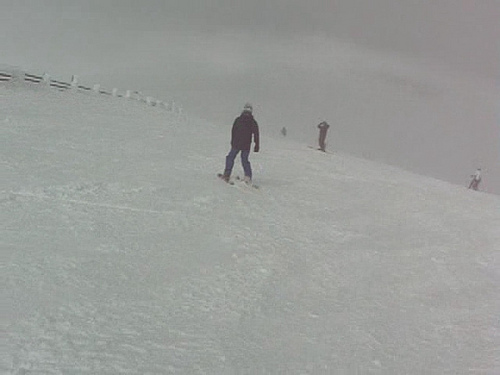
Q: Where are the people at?
A: Ski resort.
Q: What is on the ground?
A: Snow.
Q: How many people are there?
A: Four.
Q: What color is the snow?
A: White.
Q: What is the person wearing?
A: Hat.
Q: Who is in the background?
A: People.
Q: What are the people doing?
A: Skiing.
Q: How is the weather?
A: Cold.